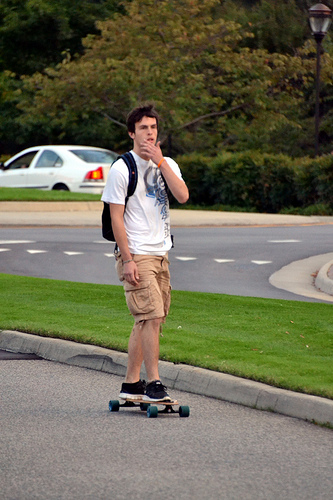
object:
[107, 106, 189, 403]
boy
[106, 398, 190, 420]
skateboard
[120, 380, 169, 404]
tennis shoes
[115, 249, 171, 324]
shorts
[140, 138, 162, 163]
band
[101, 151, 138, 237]
backpack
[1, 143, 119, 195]
car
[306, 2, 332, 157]
lamp post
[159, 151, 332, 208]
hedge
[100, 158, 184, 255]
t-shirt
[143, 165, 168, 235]
design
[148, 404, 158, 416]
wheels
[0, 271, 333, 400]
grass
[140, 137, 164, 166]
hand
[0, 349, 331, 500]
road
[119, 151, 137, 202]
strap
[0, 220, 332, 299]
road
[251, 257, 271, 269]
triangles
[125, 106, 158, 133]
hair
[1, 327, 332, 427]
curb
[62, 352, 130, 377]
mark